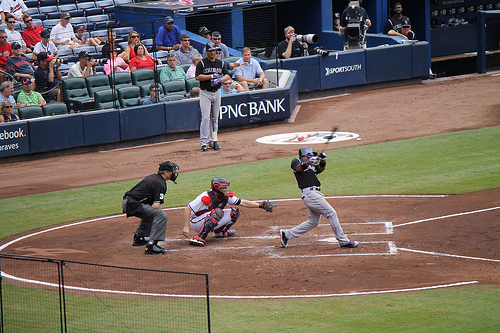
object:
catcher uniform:
[187, 176, 242, 248]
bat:
[316, 124, 341, 165]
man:
[231, 45, 271, 91]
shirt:
[231, 57, 264, 84]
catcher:
[179, 175, 278, 245]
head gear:
[208, 176, 231, 201]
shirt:
[121, 172, 169, 203]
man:
[14, 76, 47, 113]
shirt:
[15, 89, 44, 108]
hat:
[21, 76, 31, 84]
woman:
[101, 46, 131, 76]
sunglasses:
[110, 53, 117, 56]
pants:
[117, 197, 169, 239]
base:
[316, 235, 342, 242]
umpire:
[118, 160, 182, 255]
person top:
[103, 57, 130, 73]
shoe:
[131, 233, 151, 247]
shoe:
[142, 241, 167, 256]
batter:
[277, 145, 359, 248]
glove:
[257, 198, 275, 212]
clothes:
[119, 173, 169, 245]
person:
[101, 46, 130, 75]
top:
[128, 55, 157, 69]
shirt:
[103, 57, 130, 75]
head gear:
[155, 160, 180, 186]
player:
[191, 41, 252, 150]